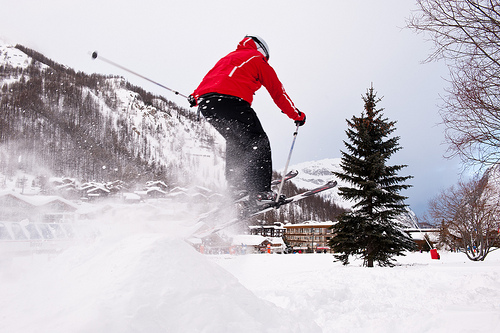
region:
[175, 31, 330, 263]
person skiing in white snow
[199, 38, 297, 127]
person wearing red jacket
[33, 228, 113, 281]
white snow on top of mountain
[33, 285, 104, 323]
white snow on top of mountain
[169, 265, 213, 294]
white snow on top of mountain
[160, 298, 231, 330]
white snow on top of mountain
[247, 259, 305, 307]
white snow on top of mountain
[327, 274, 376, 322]
white snow on top of mountain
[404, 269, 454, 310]
white snow on top of mountain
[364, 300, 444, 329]
white snow on top of mountain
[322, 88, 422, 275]
evergreen tree in the snow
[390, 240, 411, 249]
branch of the evergreen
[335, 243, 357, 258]
branch of the evergreen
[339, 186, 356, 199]
branch of the evergreen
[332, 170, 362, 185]
branch of the evergreen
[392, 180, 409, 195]
branch of the evergreen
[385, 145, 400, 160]
branch of the evergreen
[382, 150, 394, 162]
branch of the evergreen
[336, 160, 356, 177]
branch of the evergreen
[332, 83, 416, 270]
a lone evergreen tree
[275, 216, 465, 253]
a large ski lodge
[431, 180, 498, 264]
a tree with multiple trunks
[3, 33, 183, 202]
a tree covered mountain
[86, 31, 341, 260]
a skier mid jump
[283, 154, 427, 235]
a tree covered mountain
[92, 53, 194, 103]
a black ski pole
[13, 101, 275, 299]
a spray of snow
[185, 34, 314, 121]
a bright red jacket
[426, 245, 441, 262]
a bright red object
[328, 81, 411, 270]
a tall pine tree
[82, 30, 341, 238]
i skier skiing through the snow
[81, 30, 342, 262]
a skier in a red coat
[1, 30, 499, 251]
snowy mountains in the background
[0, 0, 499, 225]
clear but overcast skies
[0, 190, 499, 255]
buildings in the background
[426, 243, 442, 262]
a red box in the snow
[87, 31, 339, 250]
a skier jumping in the air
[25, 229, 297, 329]
a pile of snow in the ground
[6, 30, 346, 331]
a skier skiing off a snowy ramp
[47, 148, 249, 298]
white snow spray from skier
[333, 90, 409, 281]
stoic pine tree standing in snow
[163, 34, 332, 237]
man doing a ski jump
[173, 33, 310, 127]
red jacket with white piping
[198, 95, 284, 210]
man wearing black ski pants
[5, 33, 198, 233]
snowy and pine covered mountain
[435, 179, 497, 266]
brown tree with no leaves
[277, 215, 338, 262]
snowy brown building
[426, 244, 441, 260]
person wearing a red coat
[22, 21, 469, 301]
snowy ski resort in the mountains